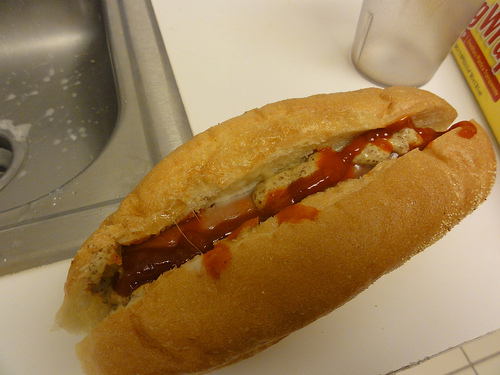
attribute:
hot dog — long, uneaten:
[58, 84, 499, 373]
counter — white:
[2, 2, 499, 374]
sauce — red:
[129, 116, 429, 278]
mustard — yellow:
[186, 150, 385, 199]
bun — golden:
[85, 79, 499, 375]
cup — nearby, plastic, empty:
[350, 0, 484, 89]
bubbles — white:
[1, 52, 99, 165]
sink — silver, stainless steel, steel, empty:
[0, 2, 182, 279]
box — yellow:
[451, 2, 500, 143]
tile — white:
[389, 342, 499, 374]